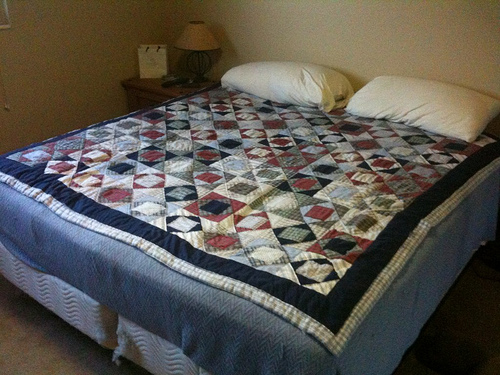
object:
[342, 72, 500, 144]
pillow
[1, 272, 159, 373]
carpet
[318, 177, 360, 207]
ground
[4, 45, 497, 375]
quilt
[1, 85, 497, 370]
blanket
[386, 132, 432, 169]
ground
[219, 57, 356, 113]
pillows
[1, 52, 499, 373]
bed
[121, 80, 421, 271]
cover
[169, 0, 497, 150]
tan wall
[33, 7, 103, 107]
wall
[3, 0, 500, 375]
room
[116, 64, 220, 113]
nightstand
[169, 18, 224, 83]
lamp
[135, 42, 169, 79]
bag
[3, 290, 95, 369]
ground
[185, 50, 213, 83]
base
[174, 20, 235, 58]
shade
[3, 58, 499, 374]
bed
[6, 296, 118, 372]
floor